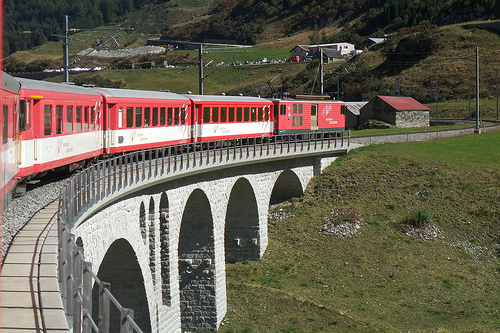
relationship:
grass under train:
[25, 36, 497, 332] [1, 65, 348, 154]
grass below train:
[25, 36, 497, 332] [1, 65, 348, 154]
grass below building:
[25, 36, 497, 332] [359, 93, 433, 131]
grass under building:
[25, 36, 497, 332] [359, 93, 433, 131]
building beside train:
[359, 93, 433, 131] [1, 65, 348, 154]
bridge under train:
[68, 146, 351, 332] [1, 65, 348, 154]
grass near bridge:
[25, 36, 497, 332] [68, 146, 351, 332]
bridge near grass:
[68, 146, 351, 332] [25, 36, 497, 332]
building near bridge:
[359, 93, 433, 131] [68, 146, 351, 332]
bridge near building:
[68, 146, 351, 332] [359, 93, 433, 131]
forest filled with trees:
[4, 0, 146, 51] [3, 0, 152, 53]